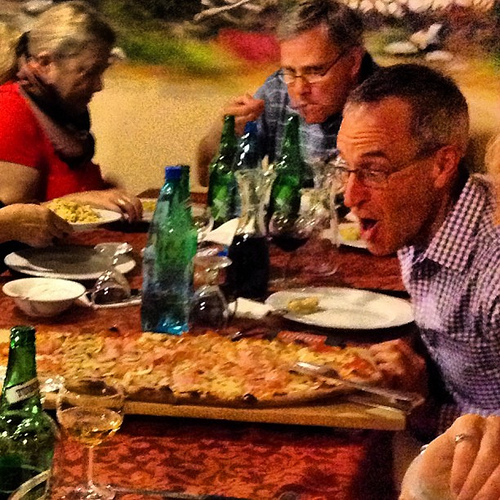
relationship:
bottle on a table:
[137, 165, 191, 336] [0, 187, 418, 425]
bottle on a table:
[208, 113, 238, 223] [0, 187, 418, 425]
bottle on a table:
[226, 115, 264, 217] [0, 187, 418, 425]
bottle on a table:
[267, 111, 304, 227] [0, 187, 418, 425]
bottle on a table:
[1, 324, 53, 499] [1, 414, 393, 499]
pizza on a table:
[2, 323, 379, 408] [0, 187, 418, 425]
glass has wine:
[269, 208, 309, 288] [269, 233, 304, 253]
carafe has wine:
[229, 170, 272, 294] [228, 233, 267, 300]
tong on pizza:
[286, 360, 423, 414] [2, 323, 379, 408]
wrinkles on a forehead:
[338, 127, 394, 152] [336, 100, 416, 167]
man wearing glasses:
[335, 64, 499, 500] [325, 147, 441, 188]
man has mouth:
[335, 64, 499, 500] [358, 214, 378, 240]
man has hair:
[335, 64, 499, 500] [342, 62, 472, 156]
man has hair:
[196, 1, 381, 186] [277, 0, 367, 48]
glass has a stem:
[269, 208, 309, 288] [277, 251, 294, 285]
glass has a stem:
[189, 254, 230, 330] [205, 269, 217, 286]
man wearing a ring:
[335, 64, 499, 500] [454, 433, 478, 445]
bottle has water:
[137, 165, 191, 336] [138, 291, 188, 332]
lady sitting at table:
[2, 3, 145, 227] [0, 187, 418, 425]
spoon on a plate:
[234, 297, 319, 338] [266, 284, 417, 332]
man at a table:
[335, 64, 499, 500] [0, 187, 418, 425]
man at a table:
[196, 1, 381, 186] [0, 187, 418, 425]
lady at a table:
[2, 3, 145, 227] [0, 187, 418, 425]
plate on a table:
[266, 284, 417, 332] [0, 187, 418, 425]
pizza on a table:
[2, 323, 379, 408] [1, 414, 393, 499]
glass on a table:
[269, 208, 309, 288] [0, 187, 418, 425]